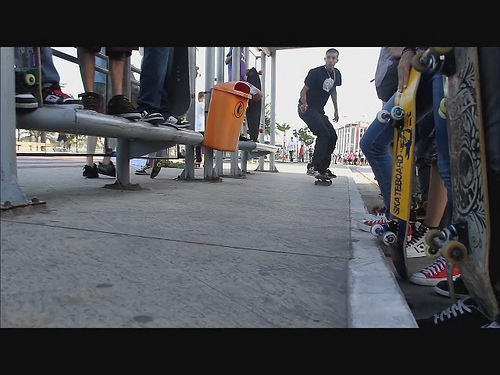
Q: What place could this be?
A: It is a sidewalk.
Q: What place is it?
A: It is a sidewalk.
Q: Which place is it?
A: It is a sidewalk.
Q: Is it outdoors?
A: Yes, it is outdoors.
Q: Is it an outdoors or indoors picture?
A: It is outdoors.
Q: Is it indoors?
A: No, it is outdoors.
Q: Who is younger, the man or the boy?
A: The boy is younger than the man.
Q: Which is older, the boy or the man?
A: The man is older than the boy.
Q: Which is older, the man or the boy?
A: The man is older than the boy.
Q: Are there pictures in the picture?
A: No, there are no pictures.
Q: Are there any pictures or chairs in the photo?
A: No, there are no pictures or chairs.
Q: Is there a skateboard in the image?
A: Yes, there is a skateboard.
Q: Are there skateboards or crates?
A: Yes, there is a skateboard.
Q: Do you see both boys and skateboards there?
A: Yes, there are both a skateboard and a boy.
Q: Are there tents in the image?
A: No, there are no tents.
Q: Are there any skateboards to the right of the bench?
A: Yes, there is a skateboard to the right of the bench.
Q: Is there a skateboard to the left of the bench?
A: No, the skateboard is to the right of the bench.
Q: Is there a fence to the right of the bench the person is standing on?
A: No, there is a skateboard to the right of the bench.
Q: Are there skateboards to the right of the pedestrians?
A: Yes, there is a skateboard to the right of the pedestrians.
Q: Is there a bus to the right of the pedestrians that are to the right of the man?
A: No, there is a skateboard to the right of the pedestrians.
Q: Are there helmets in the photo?
A: No, there are no helmets.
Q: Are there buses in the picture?
A: No, there are no buses.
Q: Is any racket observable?
A: No, there are no rackets.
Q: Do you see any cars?
A: No, there are no cars.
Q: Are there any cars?
A: No, there are no cars.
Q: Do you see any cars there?
A: No, there are no cars.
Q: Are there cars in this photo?
A: No, there are no cars.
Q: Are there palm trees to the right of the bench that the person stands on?
A: Yes, there is a palm tree to the right of the bench.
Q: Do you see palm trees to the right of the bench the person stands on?
A: Yes, there is a palm tree to the right of the bench.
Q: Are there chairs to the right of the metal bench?
A: No, there is a palm tree to the right of the bench.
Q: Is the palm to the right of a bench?
A: Yes, the palm is to the right of a bench.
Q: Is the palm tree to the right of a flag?
A: No, the palm tree is to the right of a bench.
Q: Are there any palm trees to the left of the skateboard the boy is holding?
A: Yes, there is a palm tree to the left of the skateboard.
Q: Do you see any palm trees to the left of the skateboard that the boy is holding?
A: Yes, there is a palm tree to the left of the skateboard.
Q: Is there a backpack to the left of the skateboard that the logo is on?
A: No, there is a palm tree to the left of the skateboard.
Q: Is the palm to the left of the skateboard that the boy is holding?
A: Yes, the palm is to the left of the skateboard.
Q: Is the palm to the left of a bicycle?
A: No, the palm is to the left of the skateboard.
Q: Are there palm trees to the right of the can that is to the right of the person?
A: Yes, there is a palm tree to the right of the can.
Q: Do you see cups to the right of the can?
A: No, there is a palm tree to the right of the can.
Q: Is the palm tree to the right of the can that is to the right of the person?
A: Yes, the palm tree is to the right of the can.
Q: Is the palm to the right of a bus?
A: No, the palm is to the right of the can.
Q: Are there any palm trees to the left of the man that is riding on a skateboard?
A: Yes, there is a palm tree to the left of the man.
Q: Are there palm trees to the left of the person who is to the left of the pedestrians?
A: Yes, there is a palm tree to the left of the man.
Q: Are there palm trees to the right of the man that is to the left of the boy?
A: No, the palm tree is to the left of the man.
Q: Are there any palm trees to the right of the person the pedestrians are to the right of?
A: No, the palm tree is to the left of the man.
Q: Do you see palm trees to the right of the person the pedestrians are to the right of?
A: No, the palm tree is to the left of the man.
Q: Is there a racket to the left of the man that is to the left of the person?
A: No, there is a palm tree to the left of the man.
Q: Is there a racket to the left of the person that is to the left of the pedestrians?
A: No, there is a palm tree to the left of the man.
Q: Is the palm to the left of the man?
A: Yes, the palm is to the left of the man.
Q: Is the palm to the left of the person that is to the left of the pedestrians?
A: Yes, the palm is to the left of the man.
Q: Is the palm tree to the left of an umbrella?
A: No, the palm tree is to the left of the man.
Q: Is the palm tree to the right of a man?
A: No, the palm tree is to the left of a man.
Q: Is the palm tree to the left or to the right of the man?
A: The palm tree is to the left of the man.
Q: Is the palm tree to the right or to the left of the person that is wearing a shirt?
A: The palm tree is to the left of the man.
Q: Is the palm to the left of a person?
A: Yes, the palm is to the left of a person.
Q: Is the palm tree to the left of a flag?
A: No, the palm tree is to the left of a person.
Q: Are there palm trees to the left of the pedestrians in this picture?
A: Yes, there is a palm tree to the left of the pedestrians.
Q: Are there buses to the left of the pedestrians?
A: No, there is a palm tree to the left of the pedestrians.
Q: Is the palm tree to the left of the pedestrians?
A: Yes, the palm tree is to the left of the pedestrians.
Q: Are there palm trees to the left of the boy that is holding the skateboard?
A: Yes, there is a palm tree to the left of the boy.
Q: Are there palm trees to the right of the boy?
A: No, the palm tree is to the left of the boy.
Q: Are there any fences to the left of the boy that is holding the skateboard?
A: No, there is a palm tree to the left of the boy.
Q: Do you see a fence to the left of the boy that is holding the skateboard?
A: No, there is a palm tree to the left of the boy.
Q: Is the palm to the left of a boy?
A: Yes, the palm is to the left of a boy.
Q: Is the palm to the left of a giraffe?
A: No, the palm is to the left of a boy.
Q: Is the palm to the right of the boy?
A: No, the palm is to the left of the boy.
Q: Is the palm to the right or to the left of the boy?
A: The palm is to the left of the boy.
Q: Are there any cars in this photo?
A: No, there are no cars.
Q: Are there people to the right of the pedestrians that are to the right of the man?
A: Yes, there is a person to the right of the pedestrians.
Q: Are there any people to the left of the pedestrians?
A: No, the person is to the right of the pedestrians.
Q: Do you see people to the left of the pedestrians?
A: No, the person is to the right of the pedestrians.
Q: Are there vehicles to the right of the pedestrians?
A: No, there is a person to the right of the pedestrians.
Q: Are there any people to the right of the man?
A: Yes, there is a person to the right of the man.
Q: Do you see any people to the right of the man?
A: Yes, there is a person to the right of the man.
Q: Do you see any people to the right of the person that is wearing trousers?
A: Yes, there is a person to the right of the man.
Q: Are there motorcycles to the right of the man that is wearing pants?
A: No, there is a person to the right of the man.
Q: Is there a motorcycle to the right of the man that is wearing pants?
A: No, there is a person to the right of the man.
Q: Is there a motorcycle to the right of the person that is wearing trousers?
A: No, there is a person to the right of the man.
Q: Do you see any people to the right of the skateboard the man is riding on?
A: Yes, there is a person to the right of the skateboard.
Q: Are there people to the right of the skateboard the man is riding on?
A: Yes, there is a person to the right of the skateboard.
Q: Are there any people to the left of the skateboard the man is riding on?
A: No, the person is to the right of the skateboard.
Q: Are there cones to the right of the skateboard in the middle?
A: No, there is a person to the right of the skateboard.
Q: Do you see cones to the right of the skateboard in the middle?
A: No, there is a person to the right of the skateboard.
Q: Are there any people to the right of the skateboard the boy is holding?
A: Yes, there is a person to the right of the skateboard.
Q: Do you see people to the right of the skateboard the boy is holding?
A: Yes, there is a person to the right of the skateboard.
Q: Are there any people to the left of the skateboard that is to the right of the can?
A: No, the person is to the right of the skateboard.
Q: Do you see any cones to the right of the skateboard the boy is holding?
A: No, there is a person to the right of the skateboard.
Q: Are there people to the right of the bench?
A: Yes, there is a person to the right of the bench.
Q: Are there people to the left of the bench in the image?
A: No, the person is to the right of the bench.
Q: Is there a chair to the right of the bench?
A: No, there is a person to the right of the bench.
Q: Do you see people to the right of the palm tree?
A: Yes, there is a person to the right of the palm tree.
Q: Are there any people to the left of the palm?
A: No, the person is to the right of the palm.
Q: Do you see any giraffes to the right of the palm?
A: No, there is a person to the right of the palm.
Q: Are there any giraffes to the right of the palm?
A: No, there is a person to the right of the palm.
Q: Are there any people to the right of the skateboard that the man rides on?
A: Yes, there is a person to the right of the skateboard.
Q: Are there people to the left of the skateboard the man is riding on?
A: No, the person is to the right of the skateboard.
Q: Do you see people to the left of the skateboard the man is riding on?
A: No, the person is to the right of the skateboard.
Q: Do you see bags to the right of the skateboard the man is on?
A: No, there is a person to the right of the skateboard.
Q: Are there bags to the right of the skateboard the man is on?
A: No, there is a person to the right of the skateboard.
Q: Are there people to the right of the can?
A: Yes, there is a person to the right of the can.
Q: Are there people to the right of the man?
A: Yes, there is a person to the right of the man.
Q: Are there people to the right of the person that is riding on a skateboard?
A: Yes, there is a person to the right of the man.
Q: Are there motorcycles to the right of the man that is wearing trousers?
A: No, there is a person to the right of the man.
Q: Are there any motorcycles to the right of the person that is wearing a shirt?
A: No, there is a person to the right of the man.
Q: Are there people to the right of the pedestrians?
A: Yes, there is a person to the right of the pedestrians.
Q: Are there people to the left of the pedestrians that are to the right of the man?
A: No, the person is to the right of the pedestrians.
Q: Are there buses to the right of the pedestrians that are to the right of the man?
A: No, there is a person to the right of the pedestrians.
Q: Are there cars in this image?
A: No, there are no cars.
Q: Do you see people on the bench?
A: Yes, there is a person on the bench.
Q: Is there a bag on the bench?
A: No, there is a person on the bench.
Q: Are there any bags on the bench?
A: No, there is a person on the bench.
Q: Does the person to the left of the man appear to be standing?
A: Yes, the person is standing.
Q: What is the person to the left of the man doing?
A: The person is standing.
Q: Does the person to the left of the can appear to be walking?
A: No, the person is standing.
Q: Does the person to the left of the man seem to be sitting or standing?
A: The person is standing.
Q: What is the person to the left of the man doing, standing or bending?
A: The person is standing.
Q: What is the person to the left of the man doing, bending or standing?
A: The person is standing.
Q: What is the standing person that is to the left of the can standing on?
A: The person is standing on the bench.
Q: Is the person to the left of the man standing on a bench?
A: Yes, the person is standing on a bench.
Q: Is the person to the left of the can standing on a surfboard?
A: No, the person is standing on a bench.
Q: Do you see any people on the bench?
A: Yes, there is a person on the bench.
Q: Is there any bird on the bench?
A: No, there is a person on the bench.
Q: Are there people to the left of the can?
A: Yes, there is a person to the left of the can.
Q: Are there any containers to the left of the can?
A: No, there is a person to the left of the can.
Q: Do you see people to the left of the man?
A: Yes, there is a person to the left of the man.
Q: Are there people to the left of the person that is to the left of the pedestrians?
A: Yes, there is a person to the left of the man.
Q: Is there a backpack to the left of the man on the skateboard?
A: No, there is a person to the left of the man.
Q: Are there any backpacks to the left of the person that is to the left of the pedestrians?
A: No, there is a person to the left of the man.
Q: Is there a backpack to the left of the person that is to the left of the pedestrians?
A: No, there is a person to the left of the man.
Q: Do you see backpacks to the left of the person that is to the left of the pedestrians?
A: No, there is a person to the left of the man.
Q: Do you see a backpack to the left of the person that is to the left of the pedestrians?
A: No, there is a person to the left of the man.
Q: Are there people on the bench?
A: Yes, there is a person on the bench.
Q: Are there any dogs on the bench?
A: No, there is a person on the bench.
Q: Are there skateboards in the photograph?
A: Yes, there is a skateboard.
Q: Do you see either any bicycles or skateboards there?
A: Yes, there is a skateboard.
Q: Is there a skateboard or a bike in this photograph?
A: Yes, there is a skateboard.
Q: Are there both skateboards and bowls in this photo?
A: No, there is a skateboard but no bowls.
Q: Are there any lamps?
A: No, there are no lamps.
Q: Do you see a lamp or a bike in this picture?
A: No, there are no lamps or bikes.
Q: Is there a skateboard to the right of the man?
A: Yes, there is a skateboard to the right of the man.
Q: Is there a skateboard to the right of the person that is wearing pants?
A: Yes, there is a skateboard to the right of the man.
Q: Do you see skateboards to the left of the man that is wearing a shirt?
A: No, the skateboard is to the right of the man.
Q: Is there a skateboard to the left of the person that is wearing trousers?
A: No, the skateboard is to the right of the man.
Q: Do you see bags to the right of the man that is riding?
A: No, there is a skateboard to the right of the man.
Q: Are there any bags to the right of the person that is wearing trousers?
A: No, there is a skateboard to the right of the man.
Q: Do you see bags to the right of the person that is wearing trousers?
A: No, there is a skateboard to the right of the man.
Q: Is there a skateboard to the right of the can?
A: Yes, there is a skateboard to the right of the can.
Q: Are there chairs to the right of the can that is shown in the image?
A: No, there is a skateboard to the right of the can.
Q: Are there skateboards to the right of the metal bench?
A: Yes, there is a skateboard to the right of the bench.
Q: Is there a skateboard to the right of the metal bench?
A: Yes, there is a skateboard to the right of the bench.